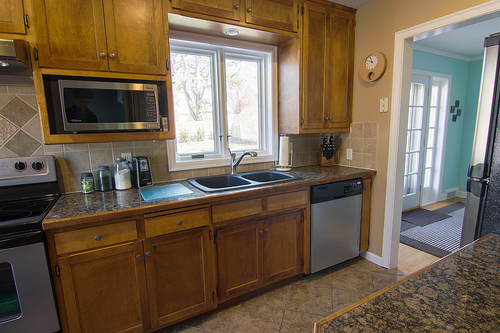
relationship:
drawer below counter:
[146, 204, 212, 236] [50, 173, 194, 214]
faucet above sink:
[227, 148, 262, 176] [188, 163, 301, 195]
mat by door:
[398, 205, 454, 228] [396, 72, 453, 215]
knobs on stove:
[11, 155, 48, 178] [1, 128, 64, 331]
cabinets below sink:
[221, 197, 309, 301] [188, 163, 301, 195]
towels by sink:
[274, 134, 297, 170] [188, 163, 301, 195]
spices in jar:
[100, 175, 108, 189] [114, 157, 133, 190]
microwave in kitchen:
[42, 75, 170, 134] [32, 14, 464, 227]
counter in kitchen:
[50, 173, 194, 214] [32, 14, 464, 227]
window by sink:
[165, 35, 273, 155] [188, 163, 301, 195]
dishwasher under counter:
[313, 179, 359, 265] [287, 164, 376, 183]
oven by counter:
[3, 227, 59, 332] [50, 173, 194, 214]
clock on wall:
[360, 53, 384, 82] [343, 12, 396, 199]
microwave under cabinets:
[42, 75, 170, 134] [25, 1, 168, 73]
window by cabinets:
[165, 35, 273, 155] [25, 1, 168, 73]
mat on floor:
[399, 202, 466, 259] [397, 240, 441, 273]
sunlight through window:
[178, 100, 195, 136] [165, 35, 273, 155]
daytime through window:
[241, 108, 256, 137] [165, 35, 273, 155]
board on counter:
[144, 181, 192, 201] [50, 173, 194, 214]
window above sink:
[165, 35, 273, 155] [188, 163, 301, 195]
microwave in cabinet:
[42, 75, 170, 134] [34, 57, 173, 83]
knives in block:
[318, 136, 337, 156] [320, 154, 336, 170]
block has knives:
[320, 154, 336, 170] [318, 136, 337, 156]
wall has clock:
[343, 12, 396, 199] [360, 53, 384, 82]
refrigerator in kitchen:
[465, 38, 499, 240] [32, 14, 464, 227]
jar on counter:
[114, 153, 134, 193] [50, 173, 194, 214]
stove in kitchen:
[1, 128, 64, 331] [32, 14, 464, 227]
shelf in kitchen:
[35, 131, 183, 145] [32, 14, 464, 227]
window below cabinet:
[165, 35, 273, 155] [246, 2, 295, 31]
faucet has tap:
[227, 148, 262, 176] [250, 146, 260, 159]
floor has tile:
[215, 275, 370, 322] [286, 286, 335, 316]